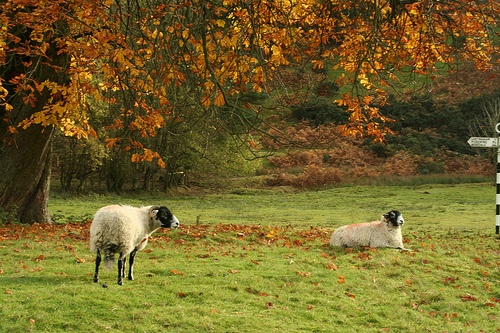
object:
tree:
[0, 0, 499, 223]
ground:
[0, 179, 499, 331]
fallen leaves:
[170, 269, 185, 275]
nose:
[173, 219, 183, 226]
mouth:
[168, 225, 181, 230]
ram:
[88, 204, 181, 285]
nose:
[397, 219, 405, 226]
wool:
[120, 210, 142, 227]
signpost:
[495, 145, 499, 235]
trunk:
[0, 16, 72, 223]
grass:
[0, 182, 499, 332]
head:
[149, 205, 180, 230]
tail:
[100, 226, 112, 275]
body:
[90, 202, 148, 285]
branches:
[202, 0, 231, 107]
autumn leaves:
[214, 96, 226, 107]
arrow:
[467, 135, 498, 148]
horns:
[147, 209, 159, 219]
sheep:
[330, 210, 406, 248]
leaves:
[313, 59, 325, 69]